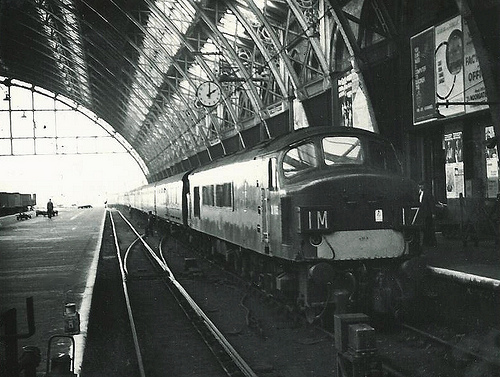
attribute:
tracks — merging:
[113, 221, 183, 288]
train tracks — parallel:
[89, 197, 434, 375]